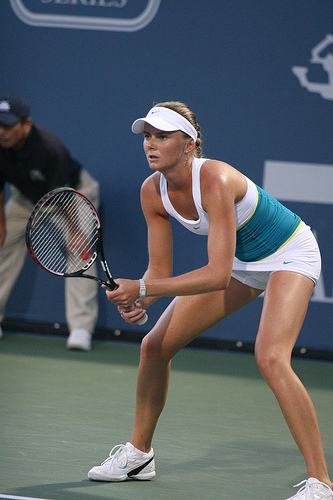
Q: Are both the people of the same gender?
A: No, they are both male and female.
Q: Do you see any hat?
A: Yes, there is a hat.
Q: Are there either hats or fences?
A: Yes, there is a hat.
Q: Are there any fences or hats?
A: Yes, there is a hat.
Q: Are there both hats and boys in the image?
A: No, there is a hat but no boys.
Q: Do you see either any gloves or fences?
A: No, there are no fences or gloves.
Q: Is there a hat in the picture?
A: Yes, there is a hat.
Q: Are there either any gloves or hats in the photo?
A: Yes, there is a hat.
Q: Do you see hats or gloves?
A: Yes, there is a hat.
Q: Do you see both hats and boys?
A: No, there is a hat but no boys.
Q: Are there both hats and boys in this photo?
A: No, there is a hat but no boys.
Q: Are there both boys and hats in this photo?
A: No, there is a hat but no boys.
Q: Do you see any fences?
A: No, there are no fences.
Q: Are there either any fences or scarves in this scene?
A: No, there are no fences or scarves.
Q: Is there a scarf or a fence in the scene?
A: No, there are no fences or scarves.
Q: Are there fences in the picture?
A: No, there are no fences.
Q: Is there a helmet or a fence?
A: No, there are no fences or helmets.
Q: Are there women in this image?
A: Yes, there is a woman.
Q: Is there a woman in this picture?
A: Yes, there is a woman.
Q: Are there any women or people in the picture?
A: Yes, there is a woman.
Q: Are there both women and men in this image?
A: Yes, there are both a woman and a man.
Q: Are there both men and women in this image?
A: Yes, there are both a woman and a man.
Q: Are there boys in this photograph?
A: No, there are no boys.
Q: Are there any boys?
A: No, there are no boys.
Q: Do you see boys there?
A: No, there are no boys.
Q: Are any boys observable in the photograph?
A: No, there are no boys.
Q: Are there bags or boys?
A: No, there are no boys or bags.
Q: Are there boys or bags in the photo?
A: No, there are no boys or bags.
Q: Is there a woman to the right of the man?
A: Yes, there is a woman to the right of the man.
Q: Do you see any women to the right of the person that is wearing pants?
A: Yes, there is a woman to the right of the man.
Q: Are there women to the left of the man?
A: No, the woman is to the right of the man.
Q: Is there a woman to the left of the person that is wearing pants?
A: No, the woman is to the right of the man.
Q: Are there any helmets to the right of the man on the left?
A: No, there is a woman to the right of the man.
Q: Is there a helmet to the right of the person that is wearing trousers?
A: No, there is a woman to the right of the man.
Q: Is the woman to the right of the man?
A: Yes, the woman is to the right of the man.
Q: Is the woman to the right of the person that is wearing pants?
A: Yes, the woman is to the right of the man.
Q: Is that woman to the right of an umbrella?
A: No, the woman is to the right of the man.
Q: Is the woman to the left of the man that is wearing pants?
A: No, the woman is to the right of the man.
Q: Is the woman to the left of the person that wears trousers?
A: No, the woman is to the right of the man.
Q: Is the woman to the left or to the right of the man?
A: The woman is to the right of the man.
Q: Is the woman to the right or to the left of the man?
A: The woman is to the right of the man.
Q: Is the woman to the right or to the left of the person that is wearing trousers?
A: The woman is to the right of the man.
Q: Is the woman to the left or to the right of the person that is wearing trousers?
A: The woman is to the right of the man.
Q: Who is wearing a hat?
A: The woman is wearing a hat.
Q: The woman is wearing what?
A: The woman is wearing a hat.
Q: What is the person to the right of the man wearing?
A: The woman is wearing a hat.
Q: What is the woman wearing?
A: The woman is wearing a hat.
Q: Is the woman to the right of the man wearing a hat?
A: Yes, the woman is wearing a hat.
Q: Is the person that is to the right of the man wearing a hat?
A: Yes, the woman is wearing a hat.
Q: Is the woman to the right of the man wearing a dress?
A: No, the woman is wearing a hat.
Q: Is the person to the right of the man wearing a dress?
A: No, the woman is wearing a hat.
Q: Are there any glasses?
A: No, there are no glasses.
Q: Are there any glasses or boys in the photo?
A: No, there are no glasses or boys.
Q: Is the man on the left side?
A: Yes, the man is on the left of the image.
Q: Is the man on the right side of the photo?
A: No, the man is on the left of the image.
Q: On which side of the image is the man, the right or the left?
A: The man is on the left of the image.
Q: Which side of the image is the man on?
A: The man is on the left of the image.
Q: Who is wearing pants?
A: The man is wearing pants.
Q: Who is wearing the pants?
A: The man is wearing pants.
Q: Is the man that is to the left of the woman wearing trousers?
A: Yes, the man is wearing trousers.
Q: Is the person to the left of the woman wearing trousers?
A: Yes, the man is wearing trousers.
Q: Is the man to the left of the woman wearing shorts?
A: No, the man is wearing trousers.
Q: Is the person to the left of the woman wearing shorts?
A: No, the man is wearing trousers.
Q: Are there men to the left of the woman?
A: Yes, there is a man to the left of the woman.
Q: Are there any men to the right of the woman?
A: No, the man is to the left of the woman.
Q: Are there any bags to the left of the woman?
A: No, there is a man to the left of the woman.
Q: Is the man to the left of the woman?
A: Yes, the man is to the left of the woman.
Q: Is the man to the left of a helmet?
A: No, the man is to the left of the woman.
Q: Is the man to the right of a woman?
A: No, the man is to the left of a woman.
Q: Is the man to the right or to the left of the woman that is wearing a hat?
A: The man is to the left of the woman.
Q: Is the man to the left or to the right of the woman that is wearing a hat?
A: The man is to the left of the woman.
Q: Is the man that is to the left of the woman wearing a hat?
A: Yes, the man is wearing a hat.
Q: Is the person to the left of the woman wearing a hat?
A: Yes, the man is wearing a hat.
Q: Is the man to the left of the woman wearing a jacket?
A: No, the man is wearing a hat.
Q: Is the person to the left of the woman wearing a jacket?
A: No, the man is wearing a hat.